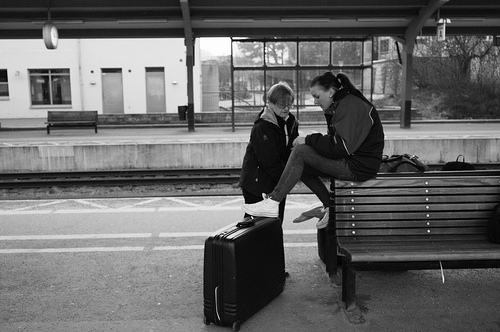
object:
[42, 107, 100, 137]
bench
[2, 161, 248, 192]
train track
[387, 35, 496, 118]
tree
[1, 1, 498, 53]
ceiling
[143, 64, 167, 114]
doors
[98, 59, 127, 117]
door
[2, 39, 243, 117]
building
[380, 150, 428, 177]
bag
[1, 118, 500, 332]
ground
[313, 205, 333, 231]
sneaker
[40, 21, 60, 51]
clock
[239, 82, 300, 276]
woman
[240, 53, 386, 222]
woman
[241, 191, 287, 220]
tennis shoe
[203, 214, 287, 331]
suitcase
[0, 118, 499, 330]
pavement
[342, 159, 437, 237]
bolt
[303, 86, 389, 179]
jacket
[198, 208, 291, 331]
suitcase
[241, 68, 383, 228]
girl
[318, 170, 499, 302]
bench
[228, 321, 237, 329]
wheel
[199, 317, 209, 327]
wheel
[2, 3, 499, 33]
roof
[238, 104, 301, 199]
dark jacket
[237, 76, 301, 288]
person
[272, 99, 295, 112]
glasses